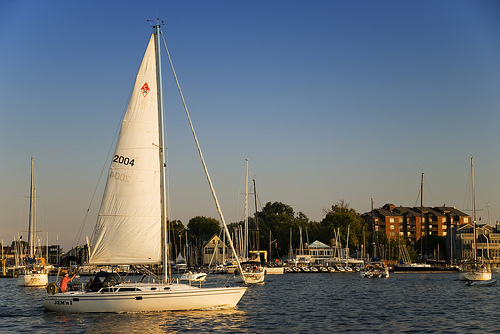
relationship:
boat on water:
[35, 11, 318, 333] [331, 285, 419, 329]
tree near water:
[237, 188, 319, 272] [331, 285, 419, 329]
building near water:
[350, 186, 480, 269] [331, 285, 419, 329]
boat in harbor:
[35, 11, 318, 333] [213, 231, 333, 286]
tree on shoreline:
[237, 188, 319, 272] [136, 236, 385, 301]